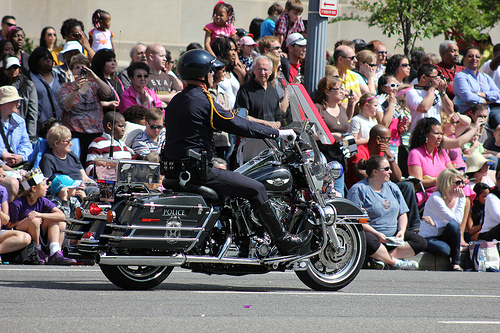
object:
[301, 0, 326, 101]
pole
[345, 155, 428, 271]
person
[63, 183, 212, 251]
saddlebags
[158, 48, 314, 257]
man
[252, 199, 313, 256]
black boot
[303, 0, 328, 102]
column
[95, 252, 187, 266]
chrome exhaust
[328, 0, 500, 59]
tree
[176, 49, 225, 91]
helmet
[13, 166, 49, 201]
gold crown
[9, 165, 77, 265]
child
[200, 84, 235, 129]
rope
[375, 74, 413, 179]
people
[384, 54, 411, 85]
people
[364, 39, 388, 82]
people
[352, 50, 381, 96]
people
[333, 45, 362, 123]
people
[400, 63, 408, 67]
sunglasses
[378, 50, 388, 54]
sunglasses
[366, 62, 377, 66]
sunglasses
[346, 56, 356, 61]
sunglasses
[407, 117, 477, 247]
person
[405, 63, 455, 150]
person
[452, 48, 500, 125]
person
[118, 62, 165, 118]
woman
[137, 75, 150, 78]
sunglasses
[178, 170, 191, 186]
handcuffs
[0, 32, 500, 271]
sidewalk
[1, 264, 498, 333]
road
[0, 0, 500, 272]
crowd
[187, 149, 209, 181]
gun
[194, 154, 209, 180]
holster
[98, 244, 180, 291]
rear tire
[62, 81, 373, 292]
motorcycle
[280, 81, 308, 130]
windshield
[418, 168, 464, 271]
lady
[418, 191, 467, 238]
blouse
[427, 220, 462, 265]
jeans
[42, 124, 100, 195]
person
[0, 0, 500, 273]
spectators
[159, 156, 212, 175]
belt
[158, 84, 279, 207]
uniform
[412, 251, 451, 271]
curb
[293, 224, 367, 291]
front tire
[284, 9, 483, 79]
background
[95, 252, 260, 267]
pipe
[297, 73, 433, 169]
seats